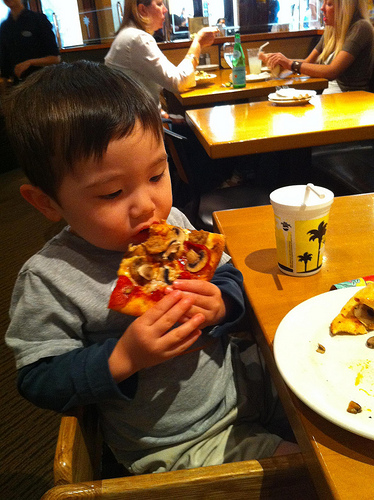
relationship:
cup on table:
[263, 168, 320, 308] [227, 188, 354, 499]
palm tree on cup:
[276, 202, 324, 261] [263, 168, 320, 308]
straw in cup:
[299, 179, 321, 207] [263, 168, 320, 308]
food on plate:
[345, 267, 373, 340] [270, 288, 372, 483]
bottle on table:
[219, 39, 260, 107] [177, 49, 318, 113]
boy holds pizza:
[19, 53, 308, 480] [102, 221, 233, 325]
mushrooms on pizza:
[129, 249, 170, 288] [102, 221, 233, 325]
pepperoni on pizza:
[107, 277, 139, 307] [102, 221, 233, 325]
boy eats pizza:
[19, 53, 308, 480] [102, 221, 233, 325]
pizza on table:
[334, 278, 373, 342] [227, 188, 354, 499]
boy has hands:
[19, 53, 308, 480] [119, 263, 235, 394]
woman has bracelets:
[269, 5, 367, 99] [289, 53, 301, 72]